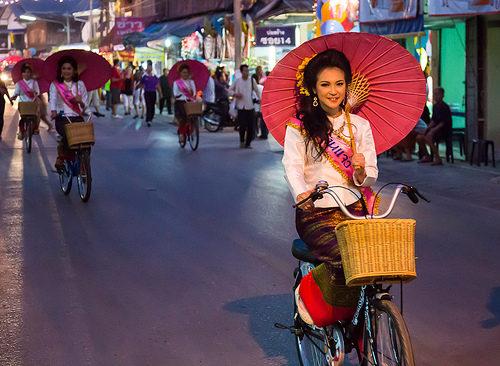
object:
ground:
[0, 87, 499, 365]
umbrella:
[260, 31, 428, 171]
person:
[280, 48, 379, 365]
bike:
[274, 180, 433, 365]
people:
[47, 55, 99, 185]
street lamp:
[17, 11, 41, 22]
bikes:
[170, 93, 210, 151]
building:
[422, 0, 499, 163]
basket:
[332, 217, 419, 286]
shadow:
[220, 292, 354, 365]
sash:
[281, 113, 381, 219]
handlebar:
[292, 185, 324, 213]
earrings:
[311, 93, 319, 108]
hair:
[293, 48, 352, 163]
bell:
[314, 180, 328, 191]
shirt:
[427, 101, 454, 129]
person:
[416, 85, 454, 167]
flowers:
[293, 52, 318, 96]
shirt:
[277, 108, 380, 208]